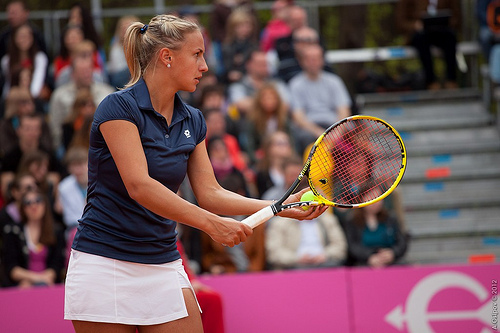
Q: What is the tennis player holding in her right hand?
A: A tennis racket.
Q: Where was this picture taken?
A: A tennis match.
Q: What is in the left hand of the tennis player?
A: A tennis ball.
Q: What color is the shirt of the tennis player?
A: Blue.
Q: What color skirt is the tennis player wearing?
A: White.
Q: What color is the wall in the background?
A: Pink.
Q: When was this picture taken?
A: Daytime.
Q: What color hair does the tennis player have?
A: Blonde.